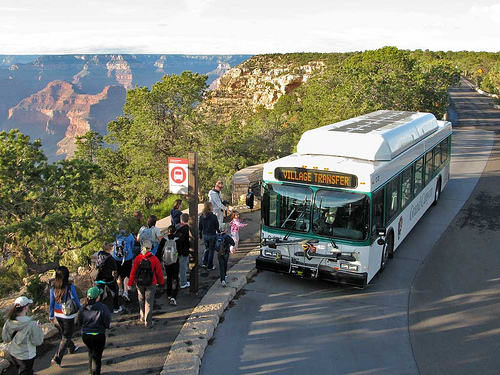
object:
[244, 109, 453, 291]
bus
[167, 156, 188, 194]
sign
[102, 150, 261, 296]
bus stop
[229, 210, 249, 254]
girl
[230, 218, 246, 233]
girl's shirt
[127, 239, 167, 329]
woman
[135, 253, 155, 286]
backpack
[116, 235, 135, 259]
woman's shirt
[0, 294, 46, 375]
person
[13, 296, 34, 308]
white cap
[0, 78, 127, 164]
mountains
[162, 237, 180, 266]
backpack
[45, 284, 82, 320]
shirt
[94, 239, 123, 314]
people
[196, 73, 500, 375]
road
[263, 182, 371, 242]
windshield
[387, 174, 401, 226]
window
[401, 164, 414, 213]
window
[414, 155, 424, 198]
window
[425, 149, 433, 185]
window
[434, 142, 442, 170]
window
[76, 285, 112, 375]
person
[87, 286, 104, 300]
green cap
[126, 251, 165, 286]
red jacket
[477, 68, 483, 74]
street sign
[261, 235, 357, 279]
bike rack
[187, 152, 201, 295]
pole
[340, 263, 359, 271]
headlight